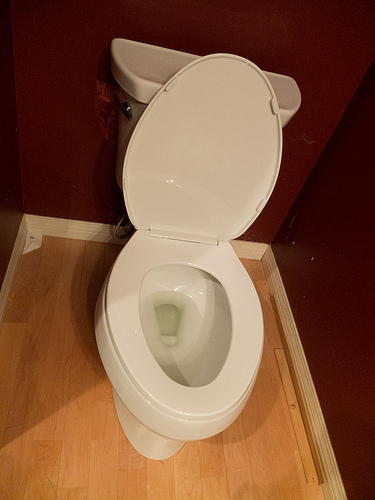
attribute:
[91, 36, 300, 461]
toilet — clean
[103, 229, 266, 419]
toilet seat — white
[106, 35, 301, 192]
toilet tank — white, porcelain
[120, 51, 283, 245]
cover — white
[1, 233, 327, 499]
floor — hardwood, light colored, finished, wood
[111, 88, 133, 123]
flush lever — silver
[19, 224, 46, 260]
toilet paper — used, white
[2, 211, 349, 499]
paneling — white, pieced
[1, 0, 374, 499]
wall — red, reddish burgundy, dark red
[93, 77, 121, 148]
flaws — white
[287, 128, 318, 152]
flaws — white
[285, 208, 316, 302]
flaws — white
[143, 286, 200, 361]
water — still, clear, low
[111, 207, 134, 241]
hose — silver